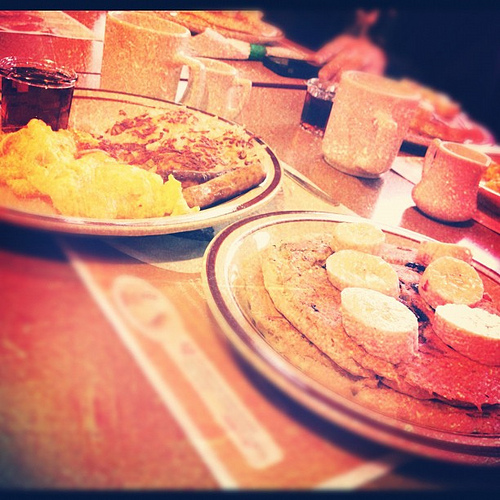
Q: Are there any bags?
A: No, there are no bags.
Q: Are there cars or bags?
A: No, there are no bags or cars.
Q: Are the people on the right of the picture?
A: Yes, the people are on the right of the image.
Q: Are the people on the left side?
A: No, the people are on the right of the image.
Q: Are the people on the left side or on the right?
A: The people are on the right of the image.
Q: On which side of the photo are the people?
A: The people are on the right of the image.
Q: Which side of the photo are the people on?
A: The people are on the right of the image.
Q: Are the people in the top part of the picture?
A: Yes, the people are in the top of the image.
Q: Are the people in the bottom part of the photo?
A: No, the people are in the top of the image.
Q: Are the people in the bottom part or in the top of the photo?
A: The people are in the top of the image.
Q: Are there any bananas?
A: Yes, there are bananas.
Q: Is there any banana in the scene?
A: Yes, there are bananas.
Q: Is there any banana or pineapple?
A: Yes, there are bananas.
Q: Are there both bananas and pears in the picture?
A: No, there are bananas but no pears.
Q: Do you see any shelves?
A: No, there are no shelves.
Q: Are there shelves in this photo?
A: No, there are no shelves.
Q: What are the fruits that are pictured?
A: The fruits are bananas.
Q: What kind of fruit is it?
A: The fruits are bananas.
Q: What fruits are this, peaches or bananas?
A: These are bananas.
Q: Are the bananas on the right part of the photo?
A: Yes, the bananas are on the right of the image.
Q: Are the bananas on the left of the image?
A: No, the bananas are on the right of the image.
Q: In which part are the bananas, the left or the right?
A: The bananas are on the right of the image.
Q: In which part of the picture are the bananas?
A: The bananas are on the right of the image.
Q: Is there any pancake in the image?
A: Yes, there is a pancake.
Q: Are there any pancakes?
A: Yes, there is a pancake.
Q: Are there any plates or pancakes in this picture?
A: Yes, there is a pancake.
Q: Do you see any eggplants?
A: No, there are no eggplants.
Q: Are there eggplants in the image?
A: No, there are no eggplants.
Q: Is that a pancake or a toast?
A: That is a pancake.